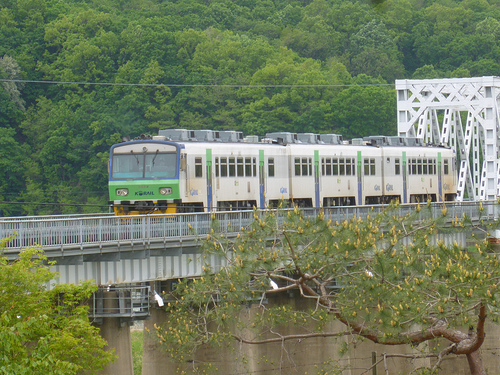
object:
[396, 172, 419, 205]
ground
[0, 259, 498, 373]
water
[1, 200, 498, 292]
tracks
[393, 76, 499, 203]
pillars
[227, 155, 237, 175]
windows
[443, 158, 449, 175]
window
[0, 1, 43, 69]
trees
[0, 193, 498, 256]
railing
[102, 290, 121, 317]
pillars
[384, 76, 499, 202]
bridge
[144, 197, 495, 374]
tree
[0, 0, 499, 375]
picture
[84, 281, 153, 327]
deck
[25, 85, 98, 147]
trees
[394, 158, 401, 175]
window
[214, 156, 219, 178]
window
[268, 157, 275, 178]
window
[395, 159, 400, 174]
window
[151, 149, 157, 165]
windsheild wiper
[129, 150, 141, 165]
windsheild wiper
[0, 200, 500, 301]
bridge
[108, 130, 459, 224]
train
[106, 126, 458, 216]
white green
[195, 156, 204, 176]
window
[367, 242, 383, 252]
flowers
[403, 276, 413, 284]
fruits